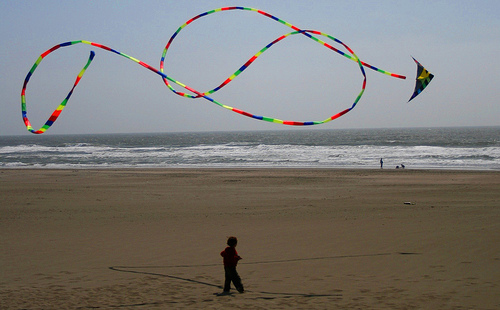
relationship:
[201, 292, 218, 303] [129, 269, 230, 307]
footprints on ground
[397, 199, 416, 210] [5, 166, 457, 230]
trash on beach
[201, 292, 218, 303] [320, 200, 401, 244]
footprints on sand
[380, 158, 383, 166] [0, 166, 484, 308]
person standing on beach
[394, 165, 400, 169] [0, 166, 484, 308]
person playing on beach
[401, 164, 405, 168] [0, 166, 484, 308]
person playing on beach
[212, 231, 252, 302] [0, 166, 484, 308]
boy playing on beach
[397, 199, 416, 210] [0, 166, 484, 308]
trash lying on beach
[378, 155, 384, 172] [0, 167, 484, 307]
person standing on shore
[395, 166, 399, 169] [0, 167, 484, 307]
person playing on shore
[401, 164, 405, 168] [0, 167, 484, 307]
person playing on shore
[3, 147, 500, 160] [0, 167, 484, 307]
wave washing on shore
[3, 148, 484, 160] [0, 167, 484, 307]
wave washing on shore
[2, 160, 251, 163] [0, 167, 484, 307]
wave washing on shore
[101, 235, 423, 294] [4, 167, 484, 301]
shadow casted on sand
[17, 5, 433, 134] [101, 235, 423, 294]
kite casting shadow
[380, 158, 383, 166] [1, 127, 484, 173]
person playing near water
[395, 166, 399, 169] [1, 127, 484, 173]
person playing near water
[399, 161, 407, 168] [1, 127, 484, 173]
person playing near water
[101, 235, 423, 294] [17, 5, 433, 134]
shadow of kite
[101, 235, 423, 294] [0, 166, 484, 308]
shadow on beach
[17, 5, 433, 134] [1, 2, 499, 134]
kite in sky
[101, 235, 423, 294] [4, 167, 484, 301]
shadow on sand